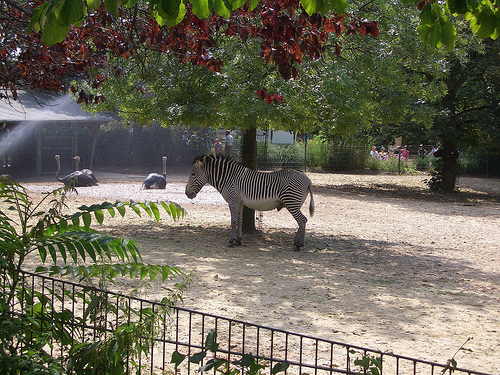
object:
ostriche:
[52, 154, 98, 187]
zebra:
[183, 152, 315, 253]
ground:
[1, 173, 499, 372]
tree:
[81, 24, 435, 234]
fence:
[6, 264, 500, 374]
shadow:
[39, 222, 487, 347]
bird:
[139, 156, 168, 190]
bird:
[54, 154, 93, 188]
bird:
[73, 155, 98, 186]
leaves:
[51, 2, 83, 27]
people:
[417, 144, 427, 156]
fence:
[261, 133, 441, 170]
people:
[214, 138, 222, 153]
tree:
[366, 4, 500, 195]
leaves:
[149, 202, 161, 222]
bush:
[0, 173, 184, 375]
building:
[0, 88, 116, 178]